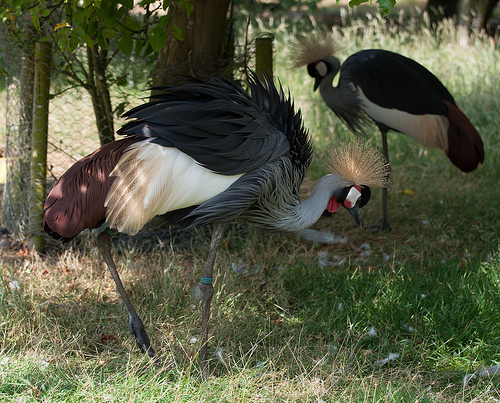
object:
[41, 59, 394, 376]
bird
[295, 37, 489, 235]
bird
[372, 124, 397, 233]
legs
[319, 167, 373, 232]
head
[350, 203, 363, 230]
beak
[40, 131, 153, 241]
tail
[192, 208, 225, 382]
right leg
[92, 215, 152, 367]
left leg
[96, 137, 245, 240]
feathers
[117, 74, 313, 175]
feathers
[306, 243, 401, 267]
feathers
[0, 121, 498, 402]
ground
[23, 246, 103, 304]
spot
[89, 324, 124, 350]
spot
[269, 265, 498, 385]
part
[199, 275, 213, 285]
band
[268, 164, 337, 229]
neck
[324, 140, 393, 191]
plume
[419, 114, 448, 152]
feathers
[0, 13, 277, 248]
fence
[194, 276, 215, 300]
right knee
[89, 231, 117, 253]
left knee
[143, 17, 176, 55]
leaves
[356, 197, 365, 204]
right eye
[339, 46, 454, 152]
wing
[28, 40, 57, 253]
stem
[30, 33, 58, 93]
part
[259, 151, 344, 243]
feathers